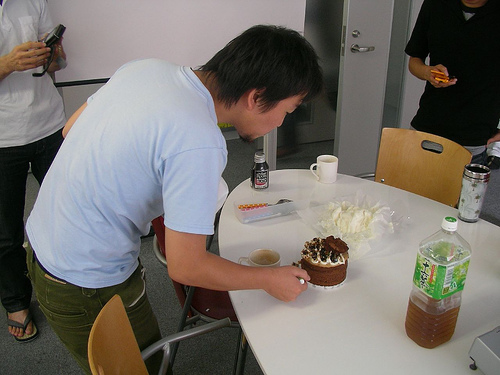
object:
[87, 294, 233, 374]
chair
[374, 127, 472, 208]
chair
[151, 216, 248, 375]
chair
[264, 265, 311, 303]
hand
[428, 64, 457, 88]
hand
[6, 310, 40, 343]
flip flops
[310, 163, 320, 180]
handle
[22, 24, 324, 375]
man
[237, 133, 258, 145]
beard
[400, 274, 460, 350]
bottle part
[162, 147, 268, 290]
arm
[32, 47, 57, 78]
strap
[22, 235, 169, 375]
pants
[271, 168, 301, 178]
table tip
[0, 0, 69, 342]
man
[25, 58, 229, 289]
shirt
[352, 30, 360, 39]
lock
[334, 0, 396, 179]
door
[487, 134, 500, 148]
hand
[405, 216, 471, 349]
bottle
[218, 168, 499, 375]
table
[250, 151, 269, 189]
bottle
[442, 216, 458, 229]
cap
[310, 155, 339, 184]
cup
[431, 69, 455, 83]
phone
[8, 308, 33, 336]
foot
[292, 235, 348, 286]
cake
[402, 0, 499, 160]
man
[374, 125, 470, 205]
back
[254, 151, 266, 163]
tip